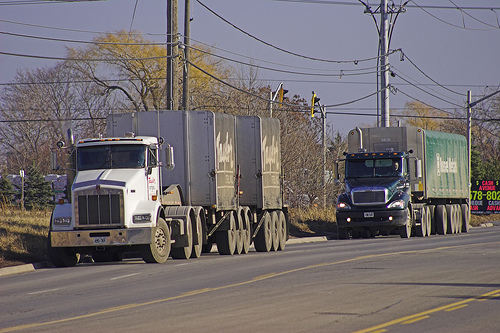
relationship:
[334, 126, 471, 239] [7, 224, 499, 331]
semi trailer on street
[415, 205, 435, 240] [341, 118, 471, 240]
tire on truck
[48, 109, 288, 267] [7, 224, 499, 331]
semi trailer on street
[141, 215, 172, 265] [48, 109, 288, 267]
tire on semi trailer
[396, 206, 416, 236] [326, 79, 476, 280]
tire on truck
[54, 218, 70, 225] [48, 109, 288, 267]
headlights on semi trailer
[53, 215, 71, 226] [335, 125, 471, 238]
light on truck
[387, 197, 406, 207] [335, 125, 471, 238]
light on truck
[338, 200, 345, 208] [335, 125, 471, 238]
light on truck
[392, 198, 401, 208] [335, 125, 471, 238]
light on truck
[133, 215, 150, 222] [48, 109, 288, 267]
light on semi trailer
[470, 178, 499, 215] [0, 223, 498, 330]
sign on side of road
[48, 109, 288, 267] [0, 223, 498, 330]
semi trailer on road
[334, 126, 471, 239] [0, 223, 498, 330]
semi trailer on road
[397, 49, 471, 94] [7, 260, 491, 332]
wires on side of road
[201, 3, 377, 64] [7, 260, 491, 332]
wires on side of road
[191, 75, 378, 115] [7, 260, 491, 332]
wires on side of road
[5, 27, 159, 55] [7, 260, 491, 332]
wires on side of road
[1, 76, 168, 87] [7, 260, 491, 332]
wires on side of road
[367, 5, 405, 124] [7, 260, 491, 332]
poles on side of road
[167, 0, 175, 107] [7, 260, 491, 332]
poles on side of road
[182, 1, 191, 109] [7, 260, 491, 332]
poles on side of road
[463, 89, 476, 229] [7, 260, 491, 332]
poles on side of road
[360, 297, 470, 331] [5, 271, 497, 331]
line on roadway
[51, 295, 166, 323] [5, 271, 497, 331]
line on roadway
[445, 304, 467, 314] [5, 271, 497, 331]
line on roadway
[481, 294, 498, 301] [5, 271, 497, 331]
line on roadway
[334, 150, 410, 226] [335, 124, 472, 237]
front of semi trailer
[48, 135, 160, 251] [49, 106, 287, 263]
front of semi trailer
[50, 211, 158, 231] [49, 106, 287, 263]
headlights on semi trailer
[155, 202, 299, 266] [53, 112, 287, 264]
tires on truck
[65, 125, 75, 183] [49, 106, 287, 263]
exhaust on semi trailer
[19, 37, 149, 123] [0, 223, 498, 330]
trees on side of road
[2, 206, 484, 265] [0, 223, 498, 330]
grass on side of road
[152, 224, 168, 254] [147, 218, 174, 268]
rim on tire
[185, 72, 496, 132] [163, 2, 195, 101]
wires and poles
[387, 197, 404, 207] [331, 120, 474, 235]
lights on truck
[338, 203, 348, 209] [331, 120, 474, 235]
light on truck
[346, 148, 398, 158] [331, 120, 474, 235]
lights on truck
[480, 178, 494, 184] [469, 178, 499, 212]
word on bulletin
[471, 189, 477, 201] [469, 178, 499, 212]
number on bulletin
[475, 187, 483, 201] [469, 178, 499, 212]
number on bulletin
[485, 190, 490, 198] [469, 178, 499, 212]
number on bulletin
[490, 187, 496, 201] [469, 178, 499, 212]
number on bulletin